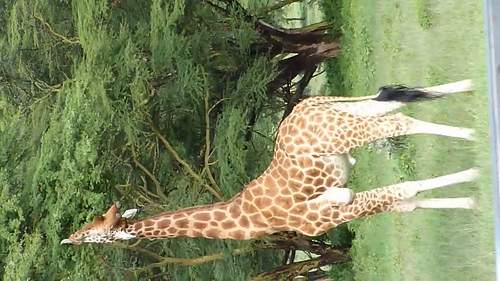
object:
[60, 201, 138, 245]
head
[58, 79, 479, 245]
giraffe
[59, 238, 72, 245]
tongue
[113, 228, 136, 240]
ear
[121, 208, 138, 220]
ear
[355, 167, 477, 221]
front legs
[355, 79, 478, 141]
back legs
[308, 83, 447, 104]
tail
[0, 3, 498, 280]
wild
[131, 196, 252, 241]
neck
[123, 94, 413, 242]
spots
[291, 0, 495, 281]
field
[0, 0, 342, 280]
branches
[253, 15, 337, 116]
trunk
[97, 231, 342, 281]
trunk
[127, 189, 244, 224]
mane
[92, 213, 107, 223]
ossicles